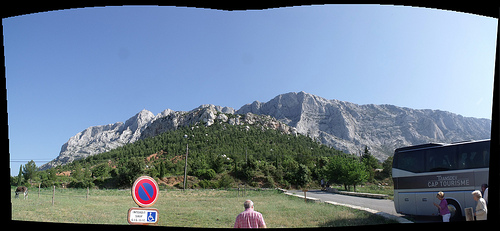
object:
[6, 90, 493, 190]
mountains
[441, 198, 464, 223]
wheel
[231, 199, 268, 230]
man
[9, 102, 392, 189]
hill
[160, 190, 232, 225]
grass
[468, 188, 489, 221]
person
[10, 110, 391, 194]
forest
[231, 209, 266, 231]
purple shirt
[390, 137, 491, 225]
bus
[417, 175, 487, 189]
writing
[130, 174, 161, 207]
circle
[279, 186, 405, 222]
road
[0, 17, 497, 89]
sky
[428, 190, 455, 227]
person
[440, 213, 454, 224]
pants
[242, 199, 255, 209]
hair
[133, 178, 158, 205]
center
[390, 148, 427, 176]
window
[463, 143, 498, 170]
window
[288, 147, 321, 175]
part